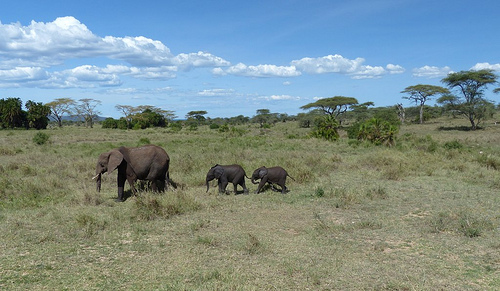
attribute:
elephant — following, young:
[204, 164, 241, 205]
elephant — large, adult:
[93, 144, 179, 204]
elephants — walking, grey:
[93, 131, 289, 211]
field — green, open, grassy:
[34, 141, 390, 272]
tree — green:
[109, 102, 170, 137]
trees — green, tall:
[6, 82, 497, 167]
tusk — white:
[94, 170, 101, 181]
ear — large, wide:
[101, 135, 130, 172]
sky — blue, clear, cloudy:
[125, 10, 341, 77]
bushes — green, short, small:
[315, 103, 421, 161]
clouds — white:
[21, 21, 144, 86]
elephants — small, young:
[200, 156, 293, 193]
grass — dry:
[166, 130, 286, 158]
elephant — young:
[253, 166, 290, 191]